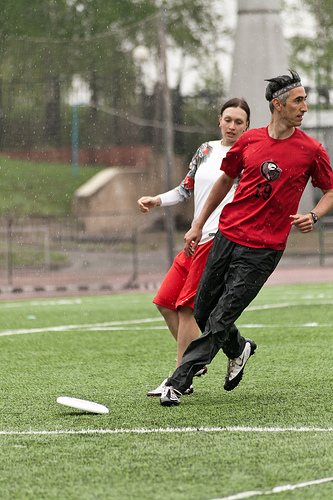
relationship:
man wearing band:
[161, 69, 331, 404] [264, 77, 309, 99]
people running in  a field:
[125, 71, 333, 402] [9, 270, 331, 496]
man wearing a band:
[161, 69, 331, 404] [264, 77, 309, 99]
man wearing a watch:
[161, 69, 331, 404] [309, 209, 323, 225]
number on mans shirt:
[249, 184, 279, 201] [221, 125, 331, 250]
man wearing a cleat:
[161, 69, 331, 404] [223, 339, 256, 389]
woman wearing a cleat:
[138, 98, 251, 383] [145, 377, 193, 393]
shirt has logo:
[217, 131, 333, 249] [250, 151, 281, 215]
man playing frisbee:
[161, 69, 331, 404] [55, 389, 109, 418]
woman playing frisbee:
[152, 92, 244, 383] [55, 389, 109, 418]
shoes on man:
[160, 341, 252, 413] [155, 337, 256, 406]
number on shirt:
[249, 184, 279, 201] [207, 113, 321, 249]